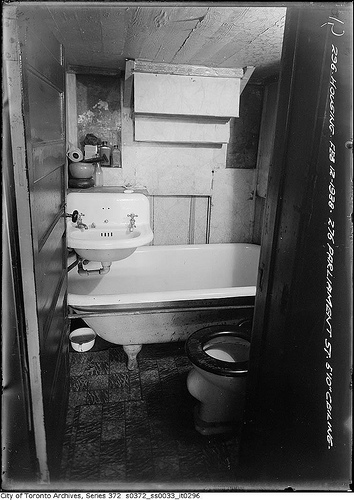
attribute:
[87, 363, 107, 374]
tile — dark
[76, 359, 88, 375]
tile — dark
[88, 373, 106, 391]
tile — dark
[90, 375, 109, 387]
tile — dark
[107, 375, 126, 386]
tile — dark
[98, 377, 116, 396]
tile — dark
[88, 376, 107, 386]
tile — dark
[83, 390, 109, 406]
tile — dark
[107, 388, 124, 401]
tile — dark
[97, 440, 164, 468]
tiles — small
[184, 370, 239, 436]
toilet — white 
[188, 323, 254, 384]
seat — black 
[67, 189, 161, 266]
sink — white 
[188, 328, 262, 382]
seat — black toilet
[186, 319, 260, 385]
seat — toilet   , down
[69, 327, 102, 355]
bowl — white  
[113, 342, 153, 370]
leg — small 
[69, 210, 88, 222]
tap — silver  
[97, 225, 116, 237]
slits — four 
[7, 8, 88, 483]
door — open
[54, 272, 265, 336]
white tub — white 